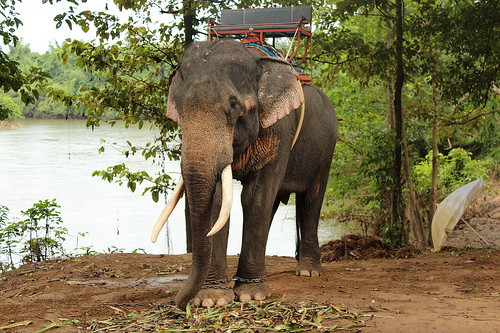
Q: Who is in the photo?
A: The elephants.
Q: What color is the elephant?
A: Brown.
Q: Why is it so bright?
A: Sunny.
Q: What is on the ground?
A: Dirt and leaves.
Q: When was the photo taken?
A: Day time.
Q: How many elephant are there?
A: One.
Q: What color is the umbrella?
A: White.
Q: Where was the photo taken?
A: On an elephant tour.